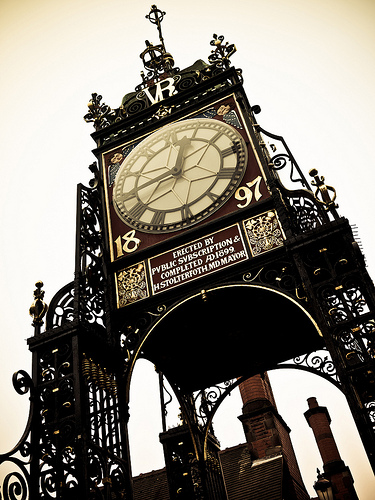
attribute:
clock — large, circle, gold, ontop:
[101, 97, 280, 243]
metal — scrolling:
[252, 104, 340, 229]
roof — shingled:
[132, 445, 292, 496]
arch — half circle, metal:
[86, 273, 350, 365]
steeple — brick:
[235, 367, 284, 448]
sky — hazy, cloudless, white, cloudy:
[2, 1, 372, 159]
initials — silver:
[142, 79, 180, 101]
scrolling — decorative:
[251, 101, 334, 224]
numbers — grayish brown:
[114, 227, 142, 258]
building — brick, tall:
[301, 388, 358, 498]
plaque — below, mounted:
[128, 212, 296, 303]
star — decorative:
[139, 147, 222, 207]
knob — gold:
[193, 286, 211, 300]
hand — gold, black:
[174, 138, 194, 172]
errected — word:
[171, 241, 205, 257]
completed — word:
[159, 258, 205, 276]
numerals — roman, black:
[218, 143, 241, 158]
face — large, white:
[121, 123, 227, 209]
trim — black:
[91, 90, 246, 137]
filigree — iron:
[88, 30, 237, 120]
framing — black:
[90, 70, 274, 212]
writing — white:
[156, 237, 239, 275]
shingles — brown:
[235, 468, 271, 486]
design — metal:
[135, 3, 179, 68]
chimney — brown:
[300, 393, 327, 414]